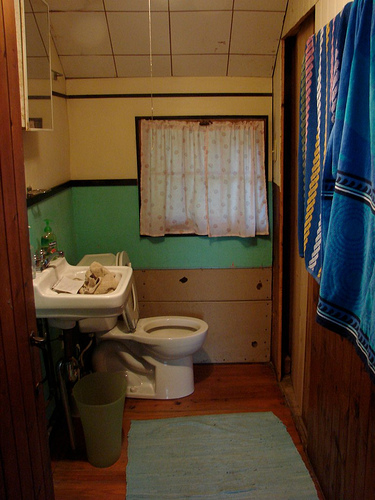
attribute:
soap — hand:
[39, 217, 58, 256]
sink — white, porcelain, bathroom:
[31, 255, 134, 338]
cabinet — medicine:
[12, 2, 59, 133]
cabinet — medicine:
[130, 265, 275, 361]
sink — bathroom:
[42, 237, 134, 323]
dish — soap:
[27, 185, 49, 196]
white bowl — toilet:
[136, 315, 208, 398]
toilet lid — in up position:
[111, 250, 139, 334]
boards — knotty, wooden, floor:
[52, 360, 322, 499]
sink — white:
[32, 262, 133, 328]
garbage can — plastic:
[68, 366, 122, 483]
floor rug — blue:
[122, 408, 320, 498]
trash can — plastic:
[76, 367, 132, 462]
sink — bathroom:
[36, 244, 126, 323]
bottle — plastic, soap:
[38, 216, 53, 258]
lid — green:
[41, 214, 51, 233]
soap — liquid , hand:
[40, 216, 60, 259]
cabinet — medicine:
[18, 4, 65, 132]